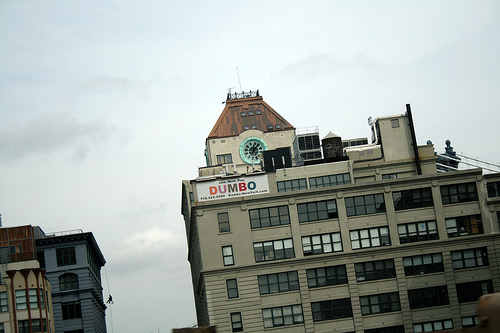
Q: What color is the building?
A: Brown.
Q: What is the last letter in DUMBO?
A: O.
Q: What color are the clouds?
A: White.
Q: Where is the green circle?
A: On top of the building.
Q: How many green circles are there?
A: One.